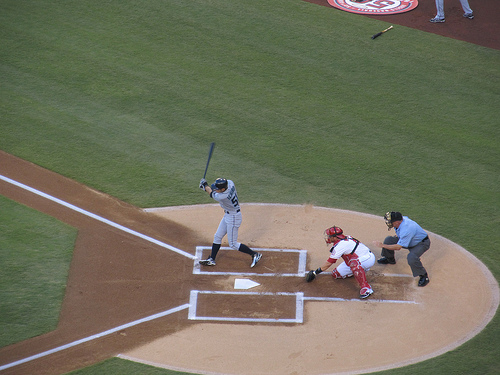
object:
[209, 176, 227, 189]
helmet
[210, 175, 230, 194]
head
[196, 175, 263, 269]
batter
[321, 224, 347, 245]
helmet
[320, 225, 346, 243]
catcher's head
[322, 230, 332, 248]
mask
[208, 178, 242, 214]
shirt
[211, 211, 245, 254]
pants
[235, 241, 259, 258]
socks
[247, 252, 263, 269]
shoes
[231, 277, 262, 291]
plate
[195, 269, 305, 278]
lines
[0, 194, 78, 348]
grass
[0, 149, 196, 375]
infield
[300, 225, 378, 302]
catcher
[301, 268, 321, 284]
glove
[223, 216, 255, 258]
leg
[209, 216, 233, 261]
leg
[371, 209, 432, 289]
person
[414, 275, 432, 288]
feet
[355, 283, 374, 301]
feet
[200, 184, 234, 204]
arm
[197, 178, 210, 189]
hand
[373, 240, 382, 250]
hand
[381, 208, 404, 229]
head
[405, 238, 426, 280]
leg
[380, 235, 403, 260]
leg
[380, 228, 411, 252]
arm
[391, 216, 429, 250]
shirt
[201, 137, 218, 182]
bat